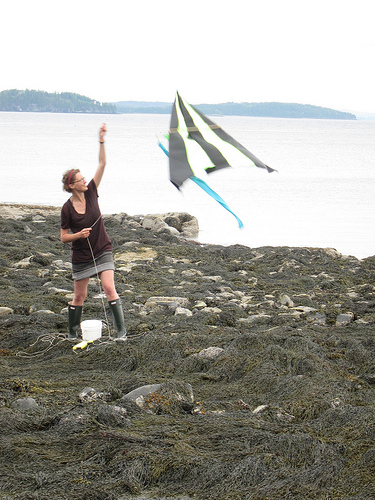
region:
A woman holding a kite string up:
[61, 122, 127, 340]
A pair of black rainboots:
[66, 303, 129, 338]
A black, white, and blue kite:
[154, 88, 276, 232]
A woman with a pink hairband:
[60, 169, 87, 196]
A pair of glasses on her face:
[74, 175, 84, 185]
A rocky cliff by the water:
[1, 199, 373, 499]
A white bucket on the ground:
[79, 316, 102, 342]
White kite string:
[14, 232, 122, 360]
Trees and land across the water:
[1, 87, 359, 123]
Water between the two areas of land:
[1, 106, 373, 253]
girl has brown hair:
[65, 154, 87, 184]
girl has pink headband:
[66, 163, 78, 192]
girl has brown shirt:
[57, 184, 106, 263]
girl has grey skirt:
[63, 254, 127, 279]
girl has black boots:
[60, 293, 144, 349]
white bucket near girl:
[83, 314, 110, 339]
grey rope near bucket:
[26, 325, 82, 386]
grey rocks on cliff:
[145, 253, 247, 333]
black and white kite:
[141, 92, 245, 185]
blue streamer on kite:
[153, 139, 268, 234]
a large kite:
[157, 89, 282, 195]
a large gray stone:
[124, 374, 195, 402]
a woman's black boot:
[106, 294, 126, 346]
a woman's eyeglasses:
[74, 170, 87, 188]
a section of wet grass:
[0, 412, 370, 498]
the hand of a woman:
[95, 117, 112, 140]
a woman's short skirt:
[62, 245, 114, 279]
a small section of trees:
[0, 88, 115, 115]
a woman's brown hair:
[61, 168, 83, 192]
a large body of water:
[0, 107, 373, 256]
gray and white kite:
[153, 89, 278, 229]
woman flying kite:
[50, 120, 134, 350]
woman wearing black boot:
[109, 298, 132, 340]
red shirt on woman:
[57, 197, 113, 253]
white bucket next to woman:
[76, 317, 105, 342]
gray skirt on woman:
[72, 252, 115, 278]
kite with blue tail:
[158, 85, 280, 228]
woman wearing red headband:
[64, 167, 76, 184]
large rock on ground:
[143, 296, 191, 326]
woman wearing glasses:
[72, 175, 96, 184]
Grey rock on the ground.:
[120, 374, 195, 416]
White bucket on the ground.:
[79, 315, 105, 343]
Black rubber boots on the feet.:
[62, 293, 128, 346]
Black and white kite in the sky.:
[162, 86, 284, 192]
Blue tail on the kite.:
[153, 136, 244, 231]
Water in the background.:
[0, 108, 373, 258]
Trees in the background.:
[0, 86, 118, 113]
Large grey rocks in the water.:
[123, 208, 199, 240]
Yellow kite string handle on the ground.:
[71, 335, 94, 353]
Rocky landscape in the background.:
[1, 221, 373, 350]